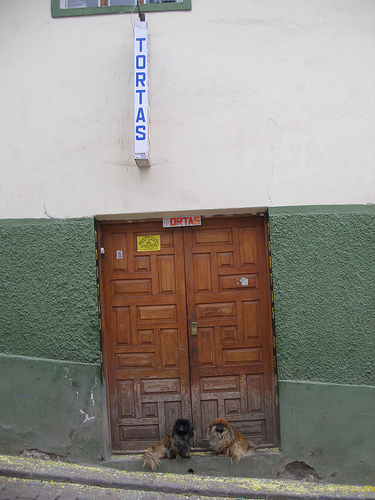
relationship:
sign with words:
[130, 20, 152, 169] [134, 36, 146, 139]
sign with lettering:
[161, 213, 203, 231] [168, 216, 203, 228]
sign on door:
[136, 234, 163, 252] [97, 215, 193, 457]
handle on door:
[191, 319, 200, 339] [181, 213, 281, 450]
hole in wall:
[278, 458, 321, 484] [1, 209, 374, 485]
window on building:
[49, 0, 194, 17] [0, 1, 375, 223]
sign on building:
[130, 20, 152, 169] [0, 1, 375, 223]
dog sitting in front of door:
[206, 414, 258, 465] [181, 213, 281, 450]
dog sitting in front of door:
[139, 415, 199, 472] [97, 215, 193, 457]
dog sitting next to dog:
[206, 414, 258, 465] [139, 415, 199, 472]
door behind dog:
[97, 215, 193, 457] [139, 415, 199, 472]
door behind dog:
[181, 213, 281, 450] [206, 414, 258, 465]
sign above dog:
[161, 213, 203, 231] [206, 414, 258, 465]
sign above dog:
[161, 213, 203, 231] [139, 415, 199, 472]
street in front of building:
[0, 453, 374, 499] [0, 1, 375, 223]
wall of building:
[1, 209, 374, 485] [0, 1, 375, 223]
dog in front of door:
[206, 414, 258, 465] [181, 213, 281, 450]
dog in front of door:
[139, 415, 199, 472] [97, 215, 193, 457]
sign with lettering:
[130, 20, 152, 169] [168, 216, 203, 228]